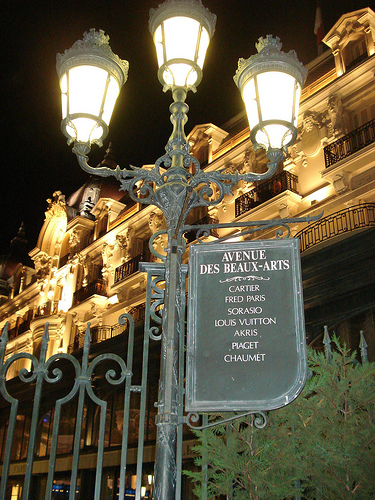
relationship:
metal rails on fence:
[8, 308, 142, 490] [3, 309, 171, 498]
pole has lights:
[135, 170, 200, 488] [43, 5, 304, 165]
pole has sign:
[135, 170, 200, 488] [187, 233, 316, 421]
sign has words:
[187, 233, 316, 421] [200, 255, 291, 366]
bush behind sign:
[220, 368, 372, 492] [187, 233, 316, 421]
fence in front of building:
[3, 309, 171, 498] [9, 170, 353, 265]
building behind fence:
[9, 170, 353, 265] [3, 309, 171, 498]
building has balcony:
[9, 170, 353, 265] [62, 257, 149, 317]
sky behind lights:
[16, 10, 145, 49] [43, 5, 304, 165]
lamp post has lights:
[71, 108, 292, 479] [43, 5, 304, 165]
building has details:
[9, 170, 353, 265] [32, 222, 146, 290]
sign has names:
[187, 233, 316, 421] [214, 282, 279, 371]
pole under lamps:
[135, 170, 200, 488] [43, 5, 304, 165]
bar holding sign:
[177, 211, 325, 241] [187, 233, 316, 421]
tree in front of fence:
[313, 343, 374, 496] [313, 321, 372, 360]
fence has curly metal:
[3, 309, 171, 498] [4, 345, 140, 412]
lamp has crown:
[225, 36, 301, 154] [252, 34, 288, 50]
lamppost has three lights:
[65, 106, 291, 234] [43, 5, 304, 165]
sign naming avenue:
[187, 233, 316, 421] [197, 245, 291, 274]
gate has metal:
[3, 309, 171, 498] [4, 345, 140, 412]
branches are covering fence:
[313, 343, 374, 496] [313, 321, 372, 360]